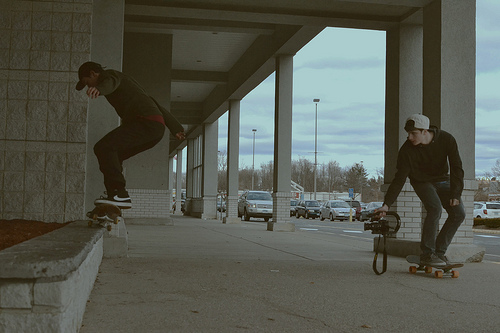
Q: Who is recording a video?
A: A skateboarder with a white hat.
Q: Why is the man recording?
A: His friend is doing a skateboard trick.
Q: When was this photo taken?
A: Daytime.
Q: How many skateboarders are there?
A: Two.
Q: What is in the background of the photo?
A: Cars, parking lot.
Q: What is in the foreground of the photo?
A: Two skateboarders.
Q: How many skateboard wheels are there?
A: Eight.